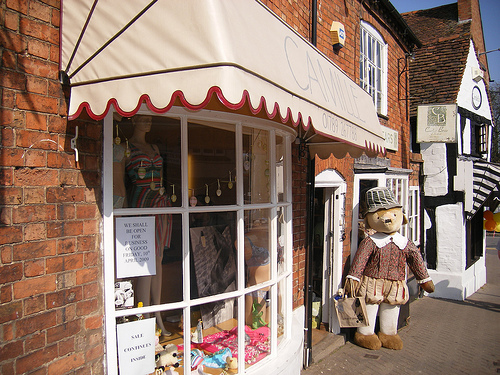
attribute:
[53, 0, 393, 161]
awning — white, cream, tan, tan+red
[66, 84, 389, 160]
trim — red, scalloped, overhanging, scallopped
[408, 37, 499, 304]
next door building — white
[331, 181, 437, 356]
teddy bear — large, brown, tall, standing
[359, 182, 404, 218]
hat — bucket-type, grey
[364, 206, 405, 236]
face — cream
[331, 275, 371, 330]
bag — brown paper bag, shopping bag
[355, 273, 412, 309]
slops — slash decorated, renaissance wear, beige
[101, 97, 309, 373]
window — white, wooden, bay window, charming, curved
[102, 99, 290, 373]
frame — wooden, white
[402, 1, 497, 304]
building — shop, white, white+black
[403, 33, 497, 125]
roof — red, reddish, tiled, shingled, brown, a little black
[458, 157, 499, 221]
awning — black, white, black+white, striped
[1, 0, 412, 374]
building — brick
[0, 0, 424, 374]
bricks — red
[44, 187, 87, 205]
brick — red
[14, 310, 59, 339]
brick — red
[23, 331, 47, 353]
brick — red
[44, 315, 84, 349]
brick — red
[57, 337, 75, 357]
brick — red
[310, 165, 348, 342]
doorway — white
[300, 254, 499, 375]
sidewalk — tiled, grey, brick, slashed, dusty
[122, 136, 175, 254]
dress — sundress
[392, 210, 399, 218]
eye — glass, round, black, plastic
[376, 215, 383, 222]
eye — round, black, glass, plastic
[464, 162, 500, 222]
stripes — black+white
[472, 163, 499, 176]
stripe — black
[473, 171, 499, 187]
stripe — black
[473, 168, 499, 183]
stripe — white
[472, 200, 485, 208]
stripe — white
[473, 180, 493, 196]
stripe — black beside white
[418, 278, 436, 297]
paw — slightly dingy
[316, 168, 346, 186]
arch — lined in white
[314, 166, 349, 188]
under-arch — wooden, door accommodation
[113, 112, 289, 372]
panes — glass, @ least 12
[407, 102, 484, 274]
detailing — black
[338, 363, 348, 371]
spot — small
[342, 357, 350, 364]
spot — small, tan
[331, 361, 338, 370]
spot — small, tan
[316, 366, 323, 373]
spot — small, tan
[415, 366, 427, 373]
spot — small, tan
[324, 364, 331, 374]
spot — tan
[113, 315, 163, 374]
sign — rectangular, on printer paper!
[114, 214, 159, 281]
sign — rectangular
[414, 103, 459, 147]
sign — grey, cream, grey+cream'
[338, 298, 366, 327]
logo — round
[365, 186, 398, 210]
stripes — white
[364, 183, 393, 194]
crown — white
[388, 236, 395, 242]
button — large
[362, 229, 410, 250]
collar — joined @ center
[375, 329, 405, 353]
foot — brown, cuddly, *bare* on bear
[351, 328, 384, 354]
foot — brown, cuddly, *bare* on bear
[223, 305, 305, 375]
building's bottom — white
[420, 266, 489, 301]
building's bottom — white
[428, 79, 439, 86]
tile — red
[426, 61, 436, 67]
tile — red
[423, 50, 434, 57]
tile — red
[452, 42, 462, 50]
tile — brown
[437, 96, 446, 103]
tile — brown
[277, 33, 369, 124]
camille — shop's name